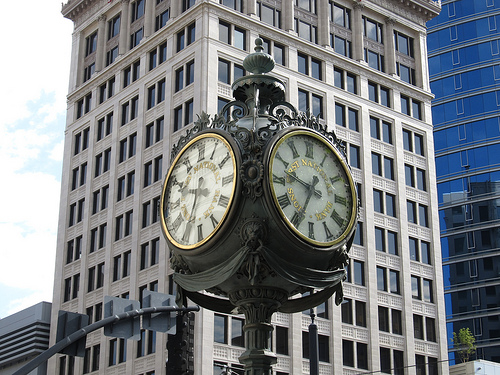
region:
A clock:
[161, 117, 351, 373]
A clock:
[233, 151, 316, 359]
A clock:
[173, 68, 273, 262]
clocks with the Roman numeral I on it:
[147, 45, 391, 288]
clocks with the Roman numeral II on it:
[152, 118, 377, 301]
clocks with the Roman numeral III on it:
[142, 127, 372, 323]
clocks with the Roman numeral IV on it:
[153, 123, 355, 305]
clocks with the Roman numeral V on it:
[135, 131, 387, 315]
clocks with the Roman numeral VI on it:
[114, 126, 388, 371]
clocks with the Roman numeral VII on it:
[92, 121, 392, 303]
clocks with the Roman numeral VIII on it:
[117, 128, 368, 331]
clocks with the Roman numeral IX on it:
[115, 128, 372, 320]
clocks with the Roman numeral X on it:
[117, 120, 359, 311]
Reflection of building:
[435, 163, 498, 351]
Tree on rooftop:
[442, 312, 494, 374]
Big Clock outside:
[136, 48, 367, 353]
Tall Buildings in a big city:
[50, 7, 496, 109]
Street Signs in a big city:
[10, 285, 215, 362]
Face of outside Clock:
[271, 130, 362, 250]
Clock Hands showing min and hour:
[280, 160, 331, 221]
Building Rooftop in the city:
[0, 292, 50, 362]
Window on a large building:
[395, 90, 423, 231]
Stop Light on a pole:
[167, 304, 212, 374]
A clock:
[133, 39, 395, 279]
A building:
[381, 253, 403, 345]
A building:
[389, 296, 414, 371]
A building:
[367, 281, 392, 333]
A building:
[382, 298, 402, 365]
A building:
[391, 268, 408, 348]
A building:
[424, 204, 444, 353]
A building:
[381, 326, 416, 370]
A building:
[348, 314, 382, 358]